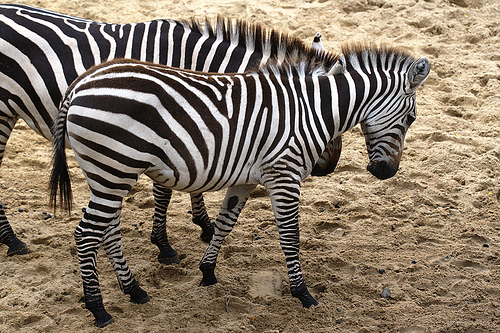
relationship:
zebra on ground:
[47, 43, 429, 329] [1, 0, 498, 325]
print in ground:
[160, 263, 188, 287] [1, 0, 498, 325]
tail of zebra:
[50, 92, 72, 221] [47, 43, 429, 329]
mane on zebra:
[257, 42, 410, 72] [47, 43, 429, 329]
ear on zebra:
[408, 57, 431, 91] [47, 43, 429, 329]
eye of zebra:
[404, 111, 415, 124] [47, 43, 429, 329]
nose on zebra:
[383, 161, 402, 180] [47, 43, 429, 329]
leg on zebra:
[266, 175, 322, 308] [47, 43, 429, 329]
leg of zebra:
[266, 175, 322, 308] [47, 43, 429, 329]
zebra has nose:
[47, 43, 429, 329] [383, 161, 402, 180]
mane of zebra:
[257, 42, 410, 72] [47, 43, 429, 329]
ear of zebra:
[408, 57, 431, 91] [47, 43, 429, 329]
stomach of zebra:
[152, 164, 238, 195] [47, 43, 429, 329]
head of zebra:
[364, 56, 429, 182] [47, 43, 429, 329]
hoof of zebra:
[92, 310, 114, 329] [47, 43, 429, 329]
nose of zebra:
[383, 161, 402, 180] [47, 43, 429, 329]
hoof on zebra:
[92, 310, 114, 329] [47, 43, 429, 329]